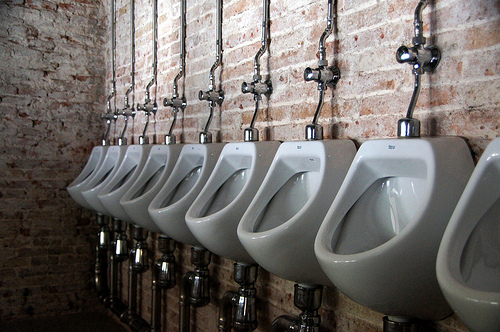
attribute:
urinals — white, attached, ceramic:
[65, 135, 493, 329]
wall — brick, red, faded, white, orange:
[3, 8, 96, 331]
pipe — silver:
[394, 4, 433, 139]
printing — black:
[294, 142, 408, 151]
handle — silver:
[299, 63, 338, 91]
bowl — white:
[315, 132, 479, 321]